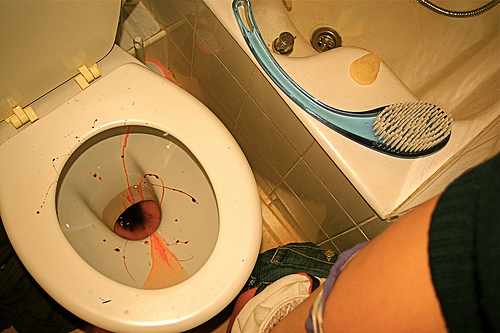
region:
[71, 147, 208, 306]
blood in the toilet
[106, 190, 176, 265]
blood in the toilet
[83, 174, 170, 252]
blood in the toilet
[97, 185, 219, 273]
blood in the toilet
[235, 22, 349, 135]
the handle is blue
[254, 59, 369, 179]
the handle is blue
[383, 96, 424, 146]
Ther eis a shower brush here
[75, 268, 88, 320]
There is a toilet here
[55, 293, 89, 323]
This photo was taken in Boise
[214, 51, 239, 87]
There are some green tiles here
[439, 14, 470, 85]
There are white showers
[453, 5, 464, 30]
There are silver shower cords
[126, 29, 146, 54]
There is a toilet brush here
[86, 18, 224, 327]
This photo is really great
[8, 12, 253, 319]
A beige toliet bowl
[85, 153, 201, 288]
Orange color in toilet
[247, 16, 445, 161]
A blue handle with beige brush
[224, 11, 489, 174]
A beige bathtub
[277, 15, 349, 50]
Silver drain in beige tub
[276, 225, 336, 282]
Jeans on the floor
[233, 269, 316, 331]
A white tennis shoe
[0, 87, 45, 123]
Yellow hinge on beige toilet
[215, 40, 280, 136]
Square beige tiles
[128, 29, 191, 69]
Handle at back of toilet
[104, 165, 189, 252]
red colors in toilet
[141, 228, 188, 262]
orange colors in toilet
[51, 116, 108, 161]
blue colors on toilet seat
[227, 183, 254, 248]
white portion of toilet seat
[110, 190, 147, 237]
water inside toilet bowl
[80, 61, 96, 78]
white hinge on toilet seat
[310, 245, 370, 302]
purple underwear on person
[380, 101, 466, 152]
white bristles on brush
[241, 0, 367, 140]
blue handle of brush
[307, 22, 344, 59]
silver faucet in bath tub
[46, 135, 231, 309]
Blood in the toilet bowl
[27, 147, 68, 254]
Blood on the toilet seat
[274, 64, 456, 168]
scrub brush on the shelf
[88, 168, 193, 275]
Blood in the toilet bowl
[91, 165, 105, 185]
Blood in the toilet bowl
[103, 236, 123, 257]
Blood in the toilet bowl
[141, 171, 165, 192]
Blood in the toilet bowl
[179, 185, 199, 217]
Blood in the toilet bowl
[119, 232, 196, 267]
Blood in the toilet bowl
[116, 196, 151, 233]
Blood in the toilet bowl